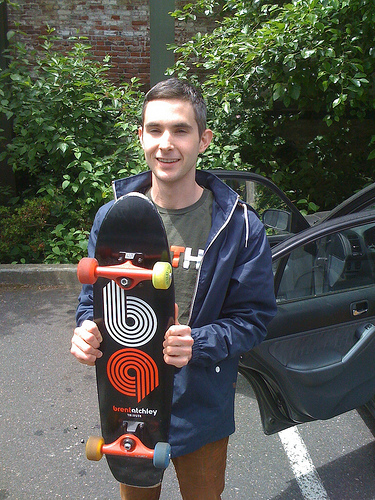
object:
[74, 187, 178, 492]
skateboard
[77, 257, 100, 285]
wheel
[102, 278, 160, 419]
design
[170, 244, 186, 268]
letters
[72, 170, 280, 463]
jacket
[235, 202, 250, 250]
tie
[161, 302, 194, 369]
hands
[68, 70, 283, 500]
man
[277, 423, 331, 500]
line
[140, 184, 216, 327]
tshirt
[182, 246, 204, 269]
h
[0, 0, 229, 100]
wall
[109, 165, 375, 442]
car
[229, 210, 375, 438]
door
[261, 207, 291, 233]
mirror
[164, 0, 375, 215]
shrub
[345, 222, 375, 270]
inside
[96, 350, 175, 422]
bottom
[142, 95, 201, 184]
face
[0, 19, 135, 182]
tree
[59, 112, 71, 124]
leaves